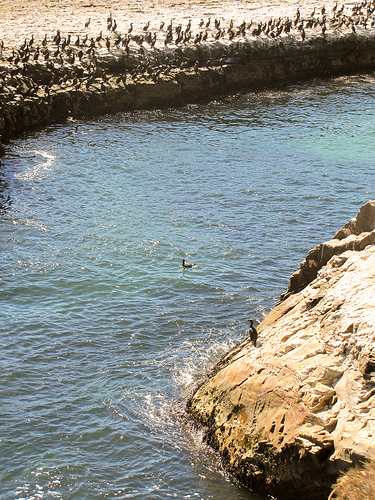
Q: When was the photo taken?
A: Day time.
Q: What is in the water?
A: Birds.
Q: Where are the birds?
A: The rocks and water.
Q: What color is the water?
A: Green.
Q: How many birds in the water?
A: One.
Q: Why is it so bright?
A: Sunny.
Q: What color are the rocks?
A: Brown.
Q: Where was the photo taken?
A: At a cove.